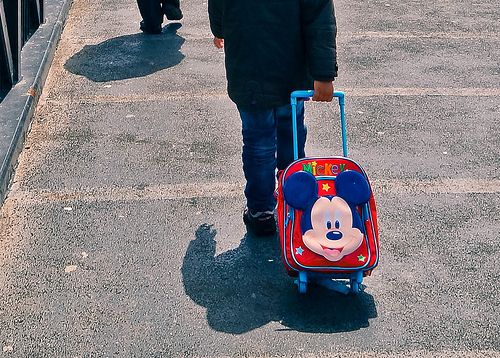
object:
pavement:
[0, 0, 500, 357]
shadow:
[180, 222, 378, 335]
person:
[207, 1, 338, 238]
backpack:
[273, 91, 380, 295]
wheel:
[293, 270, 308, 292]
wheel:
[349, 270, 366, 293]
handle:
[290, 89, 349, 161]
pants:
[237, 102, 306, 210]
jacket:
[223, 0, 339, 107]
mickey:
[283, 169, 371, 261]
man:
[136, 0, 183, 34]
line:
[60, 29, 499, 42]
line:
[38, 87, 499, 104]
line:
[3, 179, 500, 205]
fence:
[1, 0, 45, 85]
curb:
[0, 0, 55, 205]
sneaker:
[243, 202, 277, 237]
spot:
[105, 84, 112, 90]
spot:
[124, 113, 136, 119]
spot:
[64, 205, 72, 211]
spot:
[82, 251, 88, 258]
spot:
[64, 264, 79, 275]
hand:
[312, 80, 334, 101]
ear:
[282, 170, 318, 210]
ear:
[335, 169, 370, 205]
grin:
[321, 244, 344, 258]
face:
[302, 195, 365, 262]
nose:
[325, 230, 343, 241]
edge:
[248, 210, 275, 218]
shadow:
[64, 22, 185, 82]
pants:
[136, 0, 181, 19]